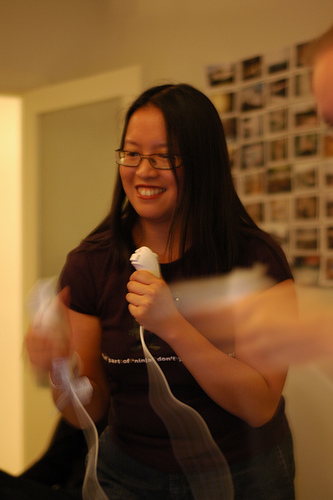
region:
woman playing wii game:
[30, 81, 305, 496]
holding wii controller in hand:
[115, 234, 179, 326]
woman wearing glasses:
[114, 80, 222, 230]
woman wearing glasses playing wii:
[27, 81, 303, 496]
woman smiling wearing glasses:
[93, 81, 249, 240]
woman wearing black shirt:
[32, 74, 302, 483]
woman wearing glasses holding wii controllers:
[27, 77, 302, 488]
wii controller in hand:
[115, 245, 180, 346]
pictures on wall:
[208, 61, 331, 277]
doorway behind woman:
[17, 61, 145, 480]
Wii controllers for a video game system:
[124, 246, 179, 359]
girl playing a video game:
[45, 42, 304, 431]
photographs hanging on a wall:
[198, 57, 329, 171]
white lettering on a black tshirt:
[92, 337, 248, 378]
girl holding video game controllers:
[12, 221, 221, 433]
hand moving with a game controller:
[219, 252, 330, 379]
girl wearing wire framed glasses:
[104, 130, 196, 176]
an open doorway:
[27, 90, 134, 230]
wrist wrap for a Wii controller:
[30, 347, 101, 415]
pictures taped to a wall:
[224, 62, 321, 180]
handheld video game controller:
[129, 245, 162, 278]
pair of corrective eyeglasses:
[113, 149, 180, 168]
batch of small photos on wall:
[202, 40, 332, 288]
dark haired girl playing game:
[20, 79, 295, 499]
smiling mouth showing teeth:
[132, 181, 168, 200]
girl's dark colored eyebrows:
[123, 138, 173, 149]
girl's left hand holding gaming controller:
[123, 269, 178, 334]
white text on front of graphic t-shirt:
[96, 353, 237, 362]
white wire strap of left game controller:
[134, 324, 235, 499]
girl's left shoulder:
[232, 227, 296, 308]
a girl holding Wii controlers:
[56, 89, 323, 493]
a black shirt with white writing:
[43, 226, 316, 486]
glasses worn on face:
[115, 140, 193, 180]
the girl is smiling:
[124, 177, 178, 212]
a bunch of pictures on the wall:
[200, 43, 331, 265]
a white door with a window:
[18, 68, 155, 479]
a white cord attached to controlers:
[44, 320, 247, 497]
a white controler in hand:
[112, 238, 204, 343]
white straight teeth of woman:
[133, 185, 170, 195]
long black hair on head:
[105, 91, 271, 307]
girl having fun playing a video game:
[13, 82, 296, 491]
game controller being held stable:
[128, 247, 160, 271]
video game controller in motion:
[34, 273, 61, 301]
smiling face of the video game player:
[114, 103, 180, 219]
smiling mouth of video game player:
[134, 184, 168, 200]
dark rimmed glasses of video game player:
[114, 149, 184, 170]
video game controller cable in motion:
[51, 363, 104, 499]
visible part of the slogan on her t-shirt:
[99, 352, 184, 365]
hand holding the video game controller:
[126, 270, 176, 328]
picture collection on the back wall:
[203, 40, 332, 286]